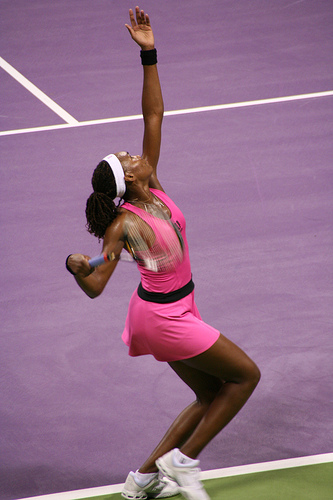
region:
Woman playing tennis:
[62, 5, 258, 497]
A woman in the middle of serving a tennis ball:
[62, 1, 260, 498]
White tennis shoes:
[119, 450, 212, 497]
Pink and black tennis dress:
[119, 188, 221, 362]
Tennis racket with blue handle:
[81, 208, 185, 272]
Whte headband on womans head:
[103, 154, 125, 196]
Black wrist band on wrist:
[140, 47, 158, 65]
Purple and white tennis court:
[261, 0, 330, 463]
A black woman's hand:
[125, 5, 156, 47]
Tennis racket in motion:
[74, 214, 187, 271]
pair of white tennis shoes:
[119, 457, 224, 498]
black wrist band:
[132, 44, 163, 68]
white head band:
[100, 152, 124, 199]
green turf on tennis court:
[249, 475, 329, 498]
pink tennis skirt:
[116, 303, 217, 364]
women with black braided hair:
[80, 138, 158, 238]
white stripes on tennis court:
[0, 49, 126, 156]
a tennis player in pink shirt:
[52, 0, 293, 499]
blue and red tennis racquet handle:
[82, 246, 111, 267]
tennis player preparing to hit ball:
[69, 3, 262, 498]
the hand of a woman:
[121, 4, 159, 48]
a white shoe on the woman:
[154, 446, 211, 498]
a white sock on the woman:
[172, 446, 198, 466]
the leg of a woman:
[143, 300, 264, 456]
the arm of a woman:
[73, 221, 125, 303]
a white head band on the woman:
[101, 151, 127, 199]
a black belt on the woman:
[133, 274, 194, 303]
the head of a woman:
[85, 147, 153, 200]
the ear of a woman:
[122, 171, 140, 182]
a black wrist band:
[137, 46, 162, 67]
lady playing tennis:
[54, 64, 292, 389]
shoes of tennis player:
[118, 452, 235, 497]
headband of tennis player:
[97, 145, 125, 198]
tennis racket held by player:
[78, 209, 191, 272]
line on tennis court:
[179, 80, 331, 118]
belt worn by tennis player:
[131, 274, 219, 305]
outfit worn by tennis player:
[122, 208, 228, 360]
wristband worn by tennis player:
[137, 45, 168, 70]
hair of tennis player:
[80, 156, 118, 232]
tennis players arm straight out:
[117, 14, 199, 189]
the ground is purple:
[252, 257, 328, 369]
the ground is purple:
[198, 246, 331, 421]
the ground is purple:
[119, 237, 305, 432]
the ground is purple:
[162, 170, 331, 454]